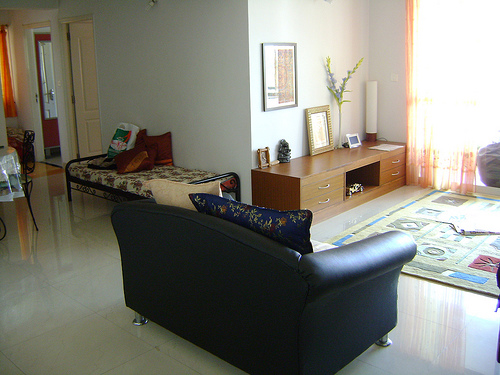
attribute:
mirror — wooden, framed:
[262, 42, 300, 110]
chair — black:
[24, 124, 42, 232]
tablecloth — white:
[1, 140, 24, 203]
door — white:
[64, 18, 107, 157]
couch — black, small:
[112, 181, 419, 375]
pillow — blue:
[190, 192, 316, 252]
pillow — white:
[147, 177, 218, 213]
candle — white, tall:
[364, 79, 385, 133]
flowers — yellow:
[323, 56, 359, 105]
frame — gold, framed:
[303, 106, 337, 157]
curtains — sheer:
[405, 1, 484, 195]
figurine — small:
[277, 141, 290, 163]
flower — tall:
[322, 52, 371, 153]